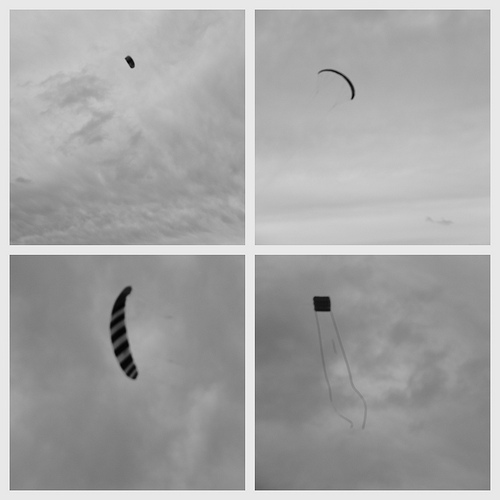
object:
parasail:
[99, 278, 145, 383]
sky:
[10, 253, 244, 492]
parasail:
[309, 59, 362, 101]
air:
[255, 10, 491, 245]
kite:
[304, 290, 372, 436]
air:
[257, 252, 491, 490]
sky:
[368, 268, 459, 383]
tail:
[308, 313, 372, 435]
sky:
[8, 10, 246, 247]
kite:
[123, 51, 138, 70]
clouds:
[10, 11, 244, 244]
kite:
[95, 270, 160, 383]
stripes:
[110, 313, 128, 358]